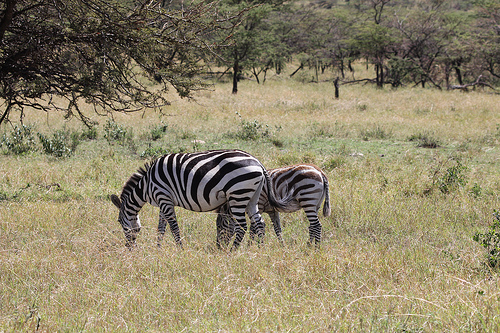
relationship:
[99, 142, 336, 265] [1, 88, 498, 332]
zebras in grass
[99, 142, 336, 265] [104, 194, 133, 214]
zebras have ears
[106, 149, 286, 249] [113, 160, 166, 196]
zebras has mane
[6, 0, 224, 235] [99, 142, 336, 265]
tree above zebras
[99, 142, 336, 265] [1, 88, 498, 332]
zebras are in grass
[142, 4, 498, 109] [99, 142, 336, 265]
trees behind zebras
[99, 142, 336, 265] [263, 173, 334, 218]
zebras have tail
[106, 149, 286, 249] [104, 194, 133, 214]
zebras has black ears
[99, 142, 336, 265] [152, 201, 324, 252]
zebras have legs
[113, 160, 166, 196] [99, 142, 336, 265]
mane on zebras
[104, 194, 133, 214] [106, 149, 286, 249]
ears on zebras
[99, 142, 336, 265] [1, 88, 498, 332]
zebras stand in grass